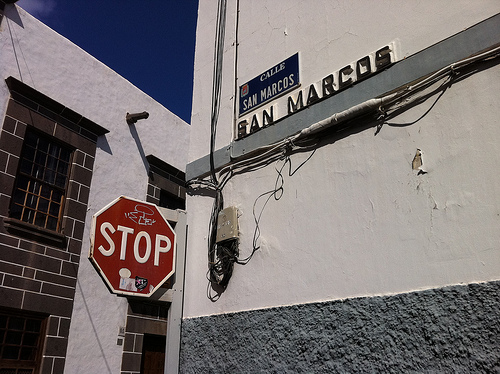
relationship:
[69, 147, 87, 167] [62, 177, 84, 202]
brick nex to brick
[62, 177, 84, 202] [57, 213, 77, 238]
brick nex to brick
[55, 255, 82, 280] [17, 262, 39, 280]
brick nex to brick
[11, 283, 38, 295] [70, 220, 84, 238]
brick nex to brick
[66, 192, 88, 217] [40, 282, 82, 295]
brick nex to brick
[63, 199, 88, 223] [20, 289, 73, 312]
brick next to brick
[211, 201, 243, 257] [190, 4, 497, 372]
electronic device on building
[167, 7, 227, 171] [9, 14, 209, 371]
border on building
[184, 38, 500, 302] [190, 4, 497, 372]
wires on building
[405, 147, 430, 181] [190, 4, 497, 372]
damage on side of building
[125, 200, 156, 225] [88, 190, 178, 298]
graffiti on red sign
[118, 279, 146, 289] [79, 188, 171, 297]
stickers stuck to sign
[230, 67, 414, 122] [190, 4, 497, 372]
letters on side of building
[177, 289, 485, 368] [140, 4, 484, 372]
stucco on side of building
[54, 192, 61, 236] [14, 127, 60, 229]
bars over window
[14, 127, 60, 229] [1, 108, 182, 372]
window of building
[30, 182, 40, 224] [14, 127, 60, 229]
bars over window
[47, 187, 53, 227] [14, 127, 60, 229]
bars over window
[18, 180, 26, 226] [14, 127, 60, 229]
bars over window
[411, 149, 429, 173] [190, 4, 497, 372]
damage in building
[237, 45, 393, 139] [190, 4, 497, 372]
letters on building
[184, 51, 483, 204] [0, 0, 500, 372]
wires on building